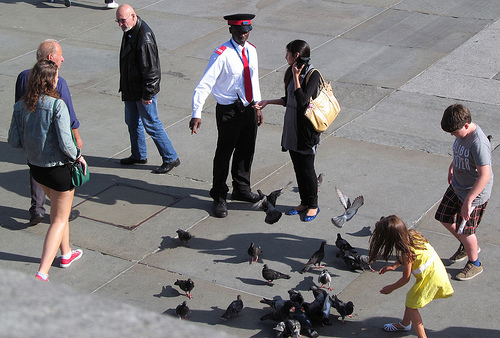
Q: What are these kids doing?
A: Feeding birds.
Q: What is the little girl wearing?
A: Yellow dress.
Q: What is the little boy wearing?
A: Shirt and shorts.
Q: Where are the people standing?
A: On a sidewalk.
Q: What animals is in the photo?
A: Birds.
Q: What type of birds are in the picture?
A: Pigeons.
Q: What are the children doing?
A: Feeding the birds.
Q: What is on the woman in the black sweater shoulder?
A: A purse.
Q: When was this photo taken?
A: In the daytime.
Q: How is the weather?
A: Sunny.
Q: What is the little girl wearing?
A: A yellow dress.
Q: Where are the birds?
A: On the ground.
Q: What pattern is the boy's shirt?
A: Plaid.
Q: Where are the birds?
A: On the ground.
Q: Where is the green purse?
A: On the leftmost woman.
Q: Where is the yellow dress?
A: On the young girl.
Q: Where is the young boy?
A: By the little girl.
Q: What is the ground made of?
A: Pavement.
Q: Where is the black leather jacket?
A: On the old man.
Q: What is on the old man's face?
A: Glasses.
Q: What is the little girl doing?
A: Feeding the birds.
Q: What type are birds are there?
A: Pigeons.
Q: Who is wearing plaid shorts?
A: The boy.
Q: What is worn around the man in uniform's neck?
A: Tie.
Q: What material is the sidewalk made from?
A: Concrete.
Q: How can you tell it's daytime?
A: It's light out.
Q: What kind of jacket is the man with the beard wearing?
A: Leather.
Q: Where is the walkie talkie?
A: The man's waist.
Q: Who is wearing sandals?
A: Little girl.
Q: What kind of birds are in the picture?
A: Pigeons.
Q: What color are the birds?
A: Black.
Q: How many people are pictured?
A: Seven.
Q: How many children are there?
A: Two.